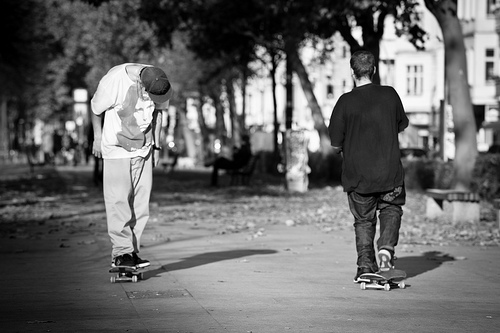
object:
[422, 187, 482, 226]
bench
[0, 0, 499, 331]
park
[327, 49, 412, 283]
skateboarder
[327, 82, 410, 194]
shirt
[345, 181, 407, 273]
jeans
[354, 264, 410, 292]
skateboard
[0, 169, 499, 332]
pavement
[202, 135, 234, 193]
man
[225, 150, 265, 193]
bench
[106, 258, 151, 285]
skateboard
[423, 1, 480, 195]
tree trunk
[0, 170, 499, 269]
leaves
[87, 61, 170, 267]
man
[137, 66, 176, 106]
head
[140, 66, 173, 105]
baseball hat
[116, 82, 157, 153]
jim morrison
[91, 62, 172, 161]
tshirt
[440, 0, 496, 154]
building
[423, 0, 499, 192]
tree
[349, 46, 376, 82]
hair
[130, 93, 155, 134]
face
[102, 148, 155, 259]
pants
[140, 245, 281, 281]
shadow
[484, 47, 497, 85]
window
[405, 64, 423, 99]
window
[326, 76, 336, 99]
window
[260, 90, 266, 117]
window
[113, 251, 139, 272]
shoe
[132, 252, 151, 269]
shoe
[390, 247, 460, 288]
shadow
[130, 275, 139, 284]
wheel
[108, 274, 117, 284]
wheel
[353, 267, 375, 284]
foot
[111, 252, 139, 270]
foot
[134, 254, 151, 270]
foot